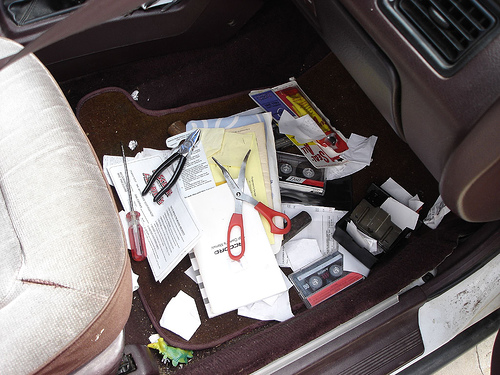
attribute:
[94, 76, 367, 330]
mat — brown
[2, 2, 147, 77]
seatbelt — red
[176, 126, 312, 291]
scissors — red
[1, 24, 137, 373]
seat — tan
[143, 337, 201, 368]
dinosaur — green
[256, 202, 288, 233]
handle — red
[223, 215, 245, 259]
handle — red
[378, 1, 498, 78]
vent — black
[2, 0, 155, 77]
seat belt — brown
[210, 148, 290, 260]
scissors — red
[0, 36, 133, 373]
car seat — grey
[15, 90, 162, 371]
seat — brown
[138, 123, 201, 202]
pliers — black, needle nose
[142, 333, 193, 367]
object — green, yellow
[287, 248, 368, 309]
tape — black, old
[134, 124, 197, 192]
pliers — black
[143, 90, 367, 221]
vent — black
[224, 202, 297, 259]
handle — red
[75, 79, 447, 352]
carpet — brown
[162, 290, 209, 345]
receipt — folded up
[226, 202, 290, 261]
handle — red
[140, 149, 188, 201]
handle — black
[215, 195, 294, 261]
handles — red